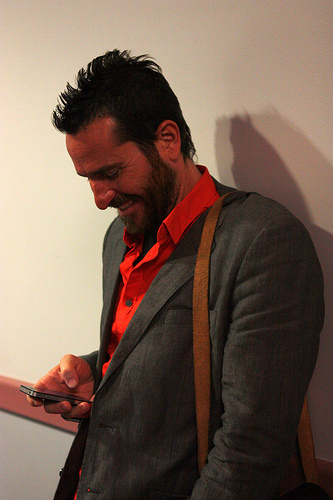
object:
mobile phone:
[19, 382, 93, 409]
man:
[28, 49, 325, 499]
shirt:
[65, 164, 220, 499]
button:
[123, 296, 133, 307]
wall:
[1, 0, 333, 499]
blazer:
[51, 176, 325, 499]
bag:
[191, 184, 323, 499]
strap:
[191, 192, 233, 474]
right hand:
[27, 354, 97, 421]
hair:
[51, 49, 198, 165]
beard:
[118, 164, 179, 237]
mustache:
[106, 193, 144, 208]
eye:
[104, 170, 122, 180]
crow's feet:
[120, 153, 141, 176]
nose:
[89, 178, 115, 211]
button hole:
[99, 421, 118, 433]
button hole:
[84, 486, 103, 497]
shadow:
[206, 104, 332, 475]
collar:
[121, 163, 215, 250]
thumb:
[58, 356, 79, 387]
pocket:
[165, 308, 219, 329]